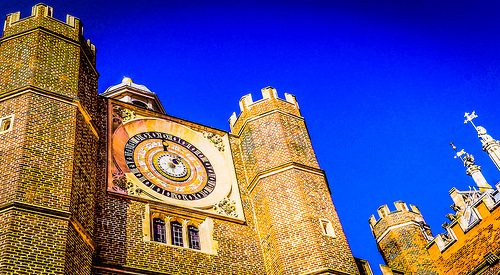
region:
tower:
[338, 172, 424, 267]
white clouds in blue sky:
[315, 16, 353, 68]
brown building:
[15, 14, 307, 258]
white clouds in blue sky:
[328, 14, 386, 90]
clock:
[101, 132, 226, 208]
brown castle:
[16, 25, 355, 273]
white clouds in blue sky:
[101, 15, 143, 50]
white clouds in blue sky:
[398, 52, 448, 93]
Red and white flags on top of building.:
[257, 73, 281, 107]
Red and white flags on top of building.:
[452, 145, 469, 157]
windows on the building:
[118, 203, 220, 273]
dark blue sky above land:
[166, 10, 453, 77]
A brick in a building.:
[23, 229, 35, 239]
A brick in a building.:
[278, 245, 289, 251]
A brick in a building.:
[283, 227, 293, 232]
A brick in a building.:
[284, 214, 290, 217]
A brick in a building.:
[284, 197, 294, 202]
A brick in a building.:
[303, 189, 310, 193]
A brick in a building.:
[306, 184, 316, 186]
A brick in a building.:
[286, 125, 293, 130]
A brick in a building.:
[291, 117, 298, 122]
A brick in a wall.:
[22, 232, 34, 239]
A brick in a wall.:
[121, 252, 128, 257]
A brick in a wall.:
[137, 259, 145, 262]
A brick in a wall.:
[288, 237, 294, 241]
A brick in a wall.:
[288, 217, 293, 221]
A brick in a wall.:
[229, 235, 236, 239]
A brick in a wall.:
[401, 236, 406, 239]